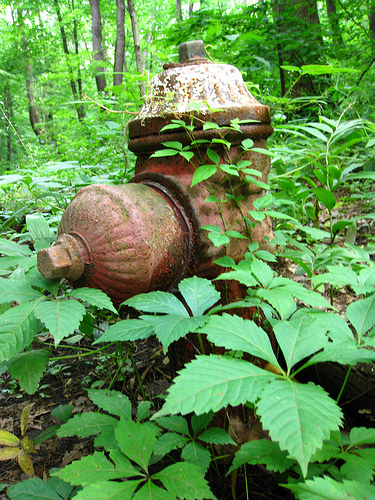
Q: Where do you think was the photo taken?
A: It was taken at the road.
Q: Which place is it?
A: It is a road.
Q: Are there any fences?
A: No, there are no fences.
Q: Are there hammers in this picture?
A: No, there are no hammers.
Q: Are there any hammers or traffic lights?
A: No, there are no hammers or traffic lights.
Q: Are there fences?
A: No, there are no fences.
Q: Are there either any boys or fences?
A: No, there are no fences or boys.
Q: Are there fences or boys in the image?
A: No, there are no fences or boys.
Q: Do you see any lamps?
A: No, there are no lamps.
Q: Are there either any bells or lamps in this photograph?
A: No, there are no lamps or bells.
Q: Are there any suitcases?
A: No, there are no suitcases.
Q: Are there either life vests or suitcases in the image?
A: No, there are no suitcases or life vests.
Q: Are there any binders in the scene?
A: No, there are no binders.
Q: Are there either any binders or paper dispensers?
A: No, there are no binders or paper dispensers.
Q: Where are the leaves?
A: The leaves are on the ground.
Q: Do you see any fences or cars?
A: No, there are no fences or cars.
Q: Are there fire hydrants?
A: Yes, there is a fire hydrant.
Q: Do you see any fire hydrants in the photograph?
A: Yes, there is a fire hydrant.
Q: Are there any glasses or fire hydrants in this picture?
A: Yes, there is a fire hydrant.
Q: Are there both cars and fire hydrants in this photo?
A: No, there is a fire hydrant but no cars.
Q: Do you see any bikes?
A: No, there are no bikes.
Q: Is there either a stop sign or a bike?
A: No, there are no bikes or stop signs.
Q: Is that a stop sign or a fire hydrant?
A: That is a fire hydrant.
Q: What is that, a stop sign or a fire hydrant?
A: That is a fire hydrant.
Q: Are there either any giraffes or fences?
A: No, there are no fences or giraffes.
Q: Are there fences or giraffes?
A: No, there are no fences or giraffes.